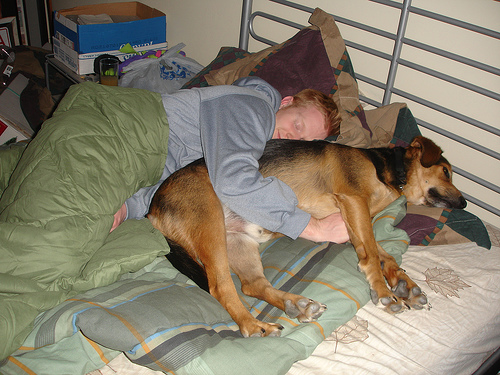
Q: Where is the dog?
A: Bed.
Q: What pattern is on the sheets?
A: Leaves.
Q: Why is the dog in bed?
A: Sleeping.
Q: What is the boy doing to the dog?
A: Hugging.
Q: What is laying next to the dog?
A: Boy.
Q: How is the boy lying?
A: On side.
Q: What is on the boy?
A: Cover.